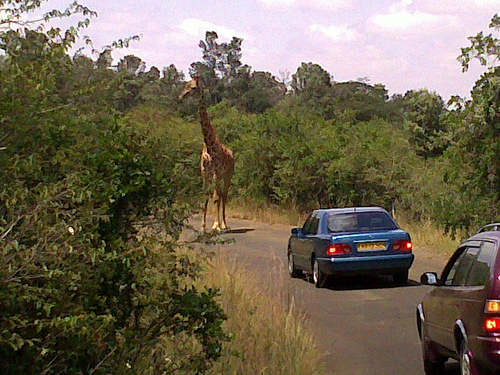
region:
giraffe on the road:
[153, 64, 255, 256]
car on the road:
[284, 200, 423, 309]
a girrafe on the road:
[167, 75, 254, 238]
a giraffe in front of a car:
[167, 64, 419, 294]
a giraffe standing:
[162, 70, 248, 265]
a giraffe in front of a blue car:
[174, 65, 421, 295]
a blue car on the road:
[285, 175, 422, 302]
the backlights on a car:
[325, 232, 415, 259]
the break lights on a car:
[322, 229, 415, 266]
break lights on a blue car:
[318, 232, 415, 267]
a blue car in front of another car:
[280, 170, 488, 374]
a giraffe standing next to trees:
[85, 35, 237, 252]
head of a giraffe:
[176, 76, 208, 106]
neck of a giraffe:
[186, 108, 218, 158]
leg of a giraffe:
[192, 199, 214, 240]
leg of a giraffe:
[212, 181, 222, 235]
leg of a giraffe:
[216, 178, 243, 225]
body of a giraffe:
[189, 142, 243, 183]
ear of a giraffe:
[187, 75, 205, 89]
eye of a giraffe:
[183, 85, 204, 96]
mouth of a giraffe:
[172, 96, 192, 114]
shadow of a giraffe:
[229, 215, 257, 259]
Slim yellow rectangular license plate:
[357, 242, 389, 251]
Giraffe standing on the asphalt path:
[175, 68, 245, 245]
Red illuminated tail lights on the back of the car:
[325, 235, 412, 260]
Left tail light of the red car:
[479, 296, 499, 334]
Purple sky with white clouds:
[0, 0, 498, 99]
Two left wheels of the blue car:
[273, 246, 328, 291]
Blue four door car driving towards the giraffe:
[273, 193, 418, 290]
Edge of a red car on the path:
[397, 220, 499, 374]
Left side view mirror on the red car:
[416, 266, 438, 286]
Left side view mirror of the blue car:
[287, 225, 303, 236]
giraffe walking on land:
[172, 80, 240, 231]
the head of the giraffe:
[177, 73, 208, 104]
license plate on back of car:
[356, 242, 391, 250]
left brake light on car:
[328, 241, 353, 257]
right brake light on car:
[388, 238, 417, 254]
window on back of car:
[330, 212, 395, 233]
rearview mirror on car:
[288, 226, 300, 236]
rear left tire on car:
[309, 256, 323, 284]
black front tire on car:
[281, 248, 296, 280]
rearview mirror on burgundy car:
[414, 269, 439, 287]